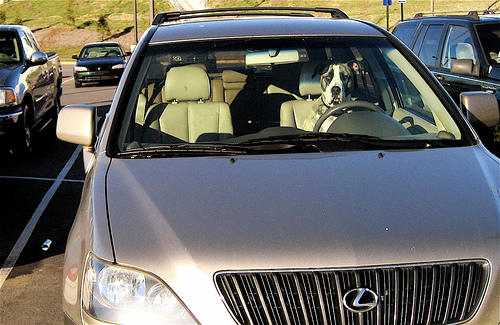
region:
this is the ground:
[8, 169, 65, 232]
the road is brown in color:
[7, 183, 33, 213]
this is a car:
[56, 17, 494, 319]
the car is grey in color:
[234, 176, 369, 236]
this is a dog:
[312, 60, 362, 123]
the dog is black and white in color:
[327, 65, 348, 71]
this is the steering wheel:
[307, 101, 394, 131]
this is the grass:
[30, 1, 54, 18]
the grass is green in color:
[23, 2, 54, 16]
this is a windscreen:
[142, 52, 274, 142]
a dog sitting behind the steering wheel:
[309, 61, 361, 126]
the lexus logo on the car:
[344, 285, 378, 313]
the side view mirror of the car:
[51, 102, 98, 169]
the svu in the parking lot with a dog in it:
[62, 8, 495, 323]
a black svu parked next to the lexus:
[391, 12, 498, 133]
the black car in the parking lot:
[71, 40, 131, 85]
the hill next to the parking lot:
[1, 0, 472, 71]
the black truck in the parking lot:
[3, 22, 64, 157]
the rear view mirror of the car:
[241, 45, 301, 65]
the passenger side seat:
[150, 61, 231, 141]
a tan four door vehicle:
[52, 6, 495, 323]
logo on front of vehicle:
[326, 277, 384, 315]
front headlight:
[71, 255, 193, 322]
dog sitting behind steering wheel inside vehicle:
[290, 51, 394, 144]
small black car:
[70, 32, 128, 95]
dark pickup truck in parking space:
[0, 17, 85, 186]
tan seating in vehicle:
[146, 51, 373, 143]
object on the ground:
[26, 223, 66, 275]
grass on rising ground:
[2, 1, 498, 55]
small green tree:
[90, 10, 120, 45]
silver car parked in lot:
[27, 4, 498, 321]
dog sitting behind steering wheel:
[222, 36, 462, 190]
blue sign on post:
[376, 0, 411, 24]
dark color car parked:
[62, 32, 143, 94]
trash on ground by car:
[35, 229, 87, 324]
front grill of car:
[182, 253, 497, 323]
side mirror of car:
[36, 100, 118, 177]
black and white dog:
[311, 61, 394, 141]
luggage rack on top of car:
[137, 4, 427, 39]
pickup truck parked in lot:
[0, 18, 70, 162]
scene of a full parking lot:
[3, 5, 498, 308]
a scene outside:
[62, 0, 474, 312]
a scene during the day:
[18, 13, 484, 286]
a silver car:
[71, 10, 489, 320]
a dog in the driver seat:
[289, 46, 369, 164]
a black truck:
[8, 17, 60, 192]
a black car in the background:
[68, 34, 164, 133]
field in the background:
[17, 1, 400, 53]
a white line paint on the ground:
[0, 83, 111, 303]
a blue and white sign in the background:
[383, 0, 411, 40]